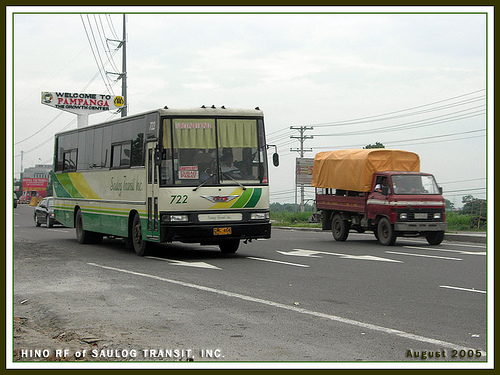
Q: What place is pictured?
A: It is a road.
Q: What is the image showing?
A: It is showing a road.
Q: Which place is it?
A: It is a road.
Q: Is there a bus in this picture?
A: Yes, there is a bus.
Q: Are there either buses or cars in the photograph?
A: Yes, there is a bus.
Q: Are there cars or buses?
A: Yes, there is a bus.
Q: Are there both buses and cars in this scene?
A: Yes, there are both a bus and a car.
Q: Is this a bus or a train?
A: This is a bus.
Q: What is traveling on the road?
A: The bus is traveling on the road.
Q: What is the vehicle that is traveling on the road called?
A: The vehicle is a bus.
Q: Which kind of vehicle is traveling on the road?
A: The vehicle is a bus.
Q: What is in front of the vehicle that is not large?
A: The bus is in front of the car.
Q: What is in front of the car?
A: The bus is in front of the car.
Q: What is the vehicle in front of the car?
A: The vehicle is a bus.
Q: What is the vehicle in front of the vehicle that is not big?
A: The vehicle is a bus.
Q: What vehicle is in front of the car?
A: The vehicle is a bus.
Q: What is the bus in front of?
A: The bus is in front of the car.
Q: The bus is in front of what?
A: The bus is in front of the car.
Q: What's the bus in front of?
A: The bus is in front of the car.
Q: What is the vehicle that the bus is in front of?
A: The vehicle is a car.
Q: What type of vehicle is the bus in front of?
A: The bus is in front of the car.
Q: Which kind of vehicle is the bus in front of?
A: The bus is in front of the car.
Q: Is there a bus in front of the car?
A: Yes, there is a bus in front of the car.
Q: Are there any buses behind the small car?
A: No, the bus is in front of the car.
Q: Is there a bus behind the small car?
A: No, the bus is in front of the car.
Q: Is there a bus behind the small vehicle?
A: No, the bus is in front of the car.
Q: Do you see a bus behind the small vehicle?
A: No, the bus is in front of the car.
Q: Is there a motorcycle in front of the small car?
A: No, there is a bus in front of the car.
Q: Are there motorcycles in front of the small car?
A: No, there is a bus in front of the car.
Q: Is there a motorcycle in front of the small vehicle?
A: No, there is a bus in front of the car.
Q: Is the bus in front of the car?
A: Yes, the bus is in front of the car.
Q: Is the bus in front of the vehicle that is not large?
A: Yes, the bus is in front of the car.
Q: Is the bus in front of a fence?
A: No, the bus is in front of the car.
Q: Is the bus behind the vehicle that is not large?
A: No, the bus is in front of the car.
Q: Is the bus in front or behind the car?
A: The bus is in front of the car.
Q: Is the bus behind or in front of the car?
A: The bus is in front of the car.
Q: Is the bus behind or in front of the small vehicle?
A: The bus is in front of the car.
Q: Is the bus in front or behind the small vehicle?
A: The bus is in front of the car.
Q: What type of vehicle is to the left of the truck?
A: The vehicle is a bus.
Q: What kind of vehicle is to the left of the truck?
A: The vehicle is a bus.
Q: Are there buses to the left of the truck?
A: Yes, there is a bus to the left of the truck.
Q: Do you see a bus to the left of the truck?
A: Yes, there is a bus to the left of the truck.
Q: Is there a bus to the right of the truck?
A: No, the bus is to the left of the truck.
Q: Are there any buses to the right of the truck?
A: No, the bus is to the left of the truck.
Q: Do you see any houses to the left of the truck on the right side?
A: No, there is a bus to the left of the truck.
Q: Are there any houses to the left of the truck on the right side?
A: No, there is a bus to the left of the truck.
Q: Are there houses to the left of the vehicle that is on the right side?
A: No, there is a bus to the left of the truck.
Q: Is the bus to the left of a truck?
A: Yes, the bus is to the left of a truck.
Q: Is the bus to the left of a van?
A: No, the bus is to the left of a truck.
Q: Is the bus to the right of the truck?
A: No, the bus is to the left of the truck.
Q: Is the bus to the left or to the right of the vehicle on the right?
A: The bus is to the left of the truck.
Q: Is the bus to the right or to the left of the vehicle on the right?
A: The bus is to the left of the truck.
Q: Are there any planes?
A: No, there are no planes.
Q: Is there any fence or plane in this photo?
A: No, there are no airplanes or fences.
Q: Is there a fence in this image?
A: No, there are no fences.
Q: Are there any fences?
A: No, there are no fences.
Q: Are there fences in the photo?
A: No, there are no fences.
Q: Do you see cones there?
A: No, there are no cones.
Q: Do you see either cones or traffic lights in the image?
A: No, there are no cones or traffic lights.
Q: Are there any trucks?
A: Yes, there is a truck.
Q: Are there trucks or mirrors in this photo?
A: Yes, there is a truck.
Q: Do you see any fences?
A: No, there are no fences.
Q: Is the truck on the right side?
A: Yes, the truck is on the right of the image.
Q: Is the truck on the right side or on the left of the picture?
A: The truck is on the right of the image.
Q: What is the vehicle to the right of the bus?
A: The vehicle is a truck.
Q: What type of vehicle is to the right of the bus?
A: The vehicle is a truck.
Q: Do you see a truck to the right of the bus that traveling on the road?
A: Yes, there is a truck to the right of the bus.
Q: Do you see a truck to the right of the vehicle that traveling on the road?
A: Yes, there is a truck to the right of the bus.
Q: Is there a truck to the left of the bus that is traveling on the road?
A: No, the truck is to the right of the bus.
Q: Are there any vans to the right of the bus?
A: No, there is a truck to the right of the bus.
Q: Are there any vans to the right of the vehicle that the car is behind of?
A: No, there is a truck to the right of the bus.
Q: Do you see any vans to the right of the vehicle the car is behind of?
A: No, there is a truck to the right of the bus.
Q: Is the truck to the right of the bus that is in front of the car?
A: Yes, the truck is to the right of the bus.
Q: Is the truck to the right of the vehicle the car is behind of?
A: Yes, the truck is to the right of the bus.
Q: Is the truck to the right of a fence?
A: No, the truck is to the right of the bus.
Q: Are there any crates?
A: No, there are no crates.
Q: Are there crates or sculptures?
A: No, there are no crates or sculptures.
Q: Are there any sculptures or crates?
A: No, there are no crates or sculptures.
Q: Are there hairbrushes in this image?
A: No, there are no hairbrushes.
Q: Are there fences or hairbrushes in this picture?
A: No, there are no hairbrushes or fences.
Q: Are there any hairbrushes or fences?
A: No, there are no hairbrushes or fences.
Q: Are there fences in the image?
A: No, there are no fences.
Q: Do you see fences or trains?
A: No, there are no fences or trains.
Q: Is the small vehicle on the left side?
A: Yes, the car is on the left of the image.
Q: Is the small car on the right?
A: No, the car is on the left of the image.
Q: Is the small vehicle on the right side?
A: No, the car is on the left of the image.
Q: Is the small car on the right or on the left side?
A: The car is on the left of the image.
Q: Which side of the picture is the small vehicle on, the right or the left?
A: The car is on the left of the image.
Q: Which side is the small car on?
A: The car is on the left of the image.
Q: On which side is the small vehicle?
A: The car is on the left of the image.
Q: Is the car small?
A: Yes, the car is small.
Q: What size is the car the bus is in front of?
A: The car is small.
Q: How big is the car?
A: The car is small.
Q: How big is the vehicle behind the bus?
A: The car is small.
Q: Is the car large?
A: No, the car is small.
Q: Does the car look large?
A: No, the car is small.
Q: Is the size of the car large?
A: No, the car is small.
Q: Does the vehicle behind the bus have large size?
A: No, the car is small.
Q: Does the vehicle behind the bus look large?
A: No, the car is small.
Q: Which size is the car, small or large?
A: The car is small.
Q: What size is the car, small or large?
A: The car is small.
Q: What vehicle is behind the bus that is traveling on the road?
A: The vehicle is a car.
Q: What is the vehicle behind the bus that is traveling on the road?
A: The vehicle is a car.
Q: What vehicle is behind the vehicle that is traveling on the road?
A: The vehicle is a car.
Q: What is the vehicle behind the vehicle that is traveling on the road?
A: The vehicle is a car.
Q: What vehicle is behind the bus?
A: The vehicle is a car.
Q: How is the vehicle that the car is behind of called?
A: The vehicle is a bus.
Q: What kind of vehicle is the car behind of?
A: The car is behind the bus.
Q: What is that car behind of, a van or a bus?
A: The car is behind a bus.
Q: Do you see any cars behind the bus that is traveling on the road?
A: Yes, there is a car behind the bus.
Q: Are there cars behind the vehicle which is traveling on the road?
A: Yes, there is a car behind the bus.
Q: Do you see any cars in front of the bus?
A: No, the car is behind the bus.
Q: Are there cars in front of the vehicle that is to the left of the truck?
A: No, the car is behind the bus.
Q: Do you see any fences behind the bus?
A: No, there is a car behind the bus.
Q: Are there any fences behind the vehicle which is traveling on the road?
A: No, there is a car behind the bus.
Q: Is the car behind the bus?
A: Yes, the car is behind the bus.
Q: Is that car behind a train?
A: No, the car is behind the bus.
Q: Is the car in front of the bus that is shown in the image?
A: No, the car is behind the bus.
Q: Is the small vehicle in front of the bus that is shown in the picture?
A: No, the car is behind the bus.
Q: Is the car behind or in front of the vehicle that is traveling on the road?
A: The car is behind the bus.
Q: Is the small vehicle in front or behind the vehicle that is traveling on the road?
A: The car is behind the bus.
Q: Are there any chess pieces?
A: No, there are no chess pieces.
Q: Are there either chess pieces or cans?
A: No, there are no chess pieces or cans.